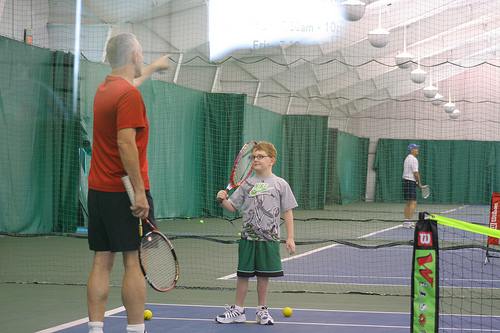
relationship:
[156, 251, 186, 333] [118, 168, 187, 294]
edge of a racket